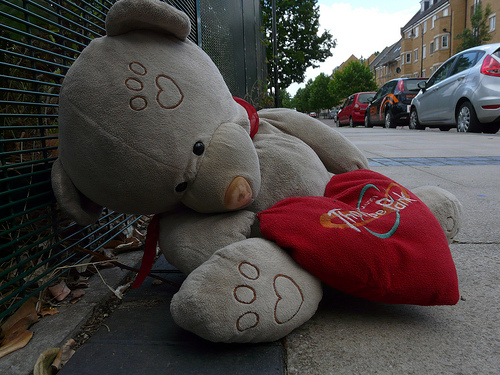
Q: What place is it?
A: It is a sidewalk.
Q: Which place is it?
A: It is a sidewalk.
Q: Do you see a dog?
A: No, there are no dogs.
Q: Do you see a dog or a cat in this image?
A: No, there are no dogs or cats.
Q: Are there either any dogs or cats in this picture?
A: No, there are no dogs or cats.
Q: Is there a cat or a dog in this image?
A: No, there are no dogs or cats.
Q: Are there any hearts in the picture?
A: Yes, there is a heart.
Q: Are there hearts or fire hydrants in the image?
A: Yes, there is a heart.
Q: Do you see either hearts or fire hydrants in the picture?
A: Yes, there is a heart.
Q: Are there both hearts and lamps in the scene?
A: No, there is a heart but no lamps.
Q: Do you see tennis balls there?
A: No, there are no tennis balls.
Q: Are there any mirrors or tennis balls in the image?
A: No, there are no tennis balls or mirrors.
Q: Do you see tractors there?
A: No, there are no tractors.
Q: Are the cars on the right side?
A: Yes, the cars are on the right of the image.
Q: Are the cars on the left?
A: No, the cars are on the right of the image.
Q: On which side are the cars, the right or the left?
A: The cars are on the right of the image.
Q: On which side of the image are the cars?
A: The cars are on the right of the image.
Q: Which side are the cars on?
A: The cars are on the right of the image.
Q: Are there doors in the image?
A: Yes, there is a door.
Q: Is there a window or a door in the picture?
A: Yes, there is a door.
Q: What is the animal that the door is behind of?
A: The animal is a bear.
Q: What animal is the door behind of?
A: The door is behind the bear.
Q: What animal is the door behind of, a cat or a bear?
A: The door is behind a bear.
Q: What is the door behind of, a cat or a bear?
A: The door is behind a bear.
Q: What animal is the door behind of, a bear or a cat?
A: The door is behind a bear.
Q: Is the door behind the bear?
A: Yes, the door is behind the bear.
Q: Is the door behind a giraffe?
A: No, the door is behind the bear.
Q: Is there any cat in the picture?
A: No, there are no cats.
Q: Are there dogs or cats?
A: No, there are no cats or dogs.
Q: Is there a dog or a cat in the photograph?
A: No, there are no cats or dogs.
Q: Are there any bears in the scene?
A: Yes, there is a bear.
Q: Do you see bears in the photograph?
A: Yes, there is a bear.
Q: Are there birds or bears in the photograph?
A: Yes, there is a bear.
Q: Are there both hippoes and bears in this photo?
A: No, there is a bear but no hippoes.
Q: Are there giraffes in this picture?
A: No, there are no giraffes.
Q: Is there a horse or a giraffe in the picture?
A: No, there are no giraffes or horses.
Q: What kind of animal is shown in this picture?
A: The animal is a bear.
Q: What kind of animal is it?
A: The animal is a bear.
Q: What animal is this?
A: This is a bear.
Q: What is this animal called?
A: This is a bear.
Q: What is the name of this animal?
A: This is a bear.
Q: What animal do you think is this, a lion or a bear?
A: This is a bear.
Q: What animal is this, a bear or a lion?
A: This is a bear.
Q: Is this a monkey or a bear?
A: This is a bear.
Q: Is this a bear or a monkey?
A: This is a bear.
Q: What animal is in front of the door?
A: The bear is in front of the door.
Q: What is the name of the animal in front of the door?
A: The animal is a bear.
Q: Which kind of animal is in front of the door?
A: The animal is a bear.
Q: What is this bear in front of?
A: The bear is in front of the door.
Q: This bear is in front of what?
A: The bear is in front of the door.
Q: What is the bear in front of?
A: The bear is in front of the door.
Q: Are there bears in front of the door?
A: Yes, there is a bear in front of the door.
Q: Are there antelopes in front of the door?
A: No, there is a bear in front of the door.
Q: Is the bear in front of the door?
A: Yes, the bear is in front of the door.